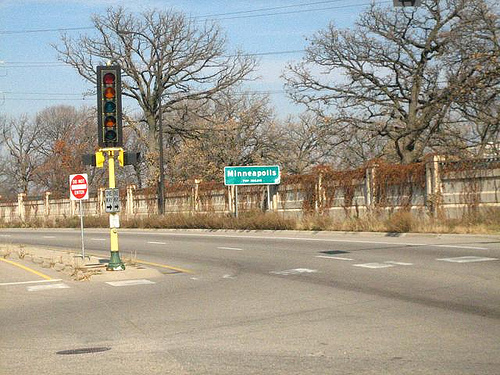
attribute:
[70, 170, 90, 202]
sign — red, white 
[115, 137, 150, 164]
sign — peatonal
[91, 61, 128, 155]
light — off, traffic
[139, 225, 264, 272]
lines — white, dotted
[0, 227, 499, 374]
street — empty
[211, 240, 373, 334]
street — paved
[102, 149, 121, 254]
pole — yellow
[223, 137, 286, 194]
sign — peatonal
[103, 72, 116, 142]
lights — dark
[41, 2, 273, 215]
tree — bare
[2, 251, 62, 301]
stripe — yellow 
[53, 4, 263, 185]
tree — bare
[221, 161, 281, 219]
sign — city limits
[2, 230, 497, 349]
street — paved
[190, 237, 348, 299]
street — paved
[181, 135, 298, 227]
sign — long, rectangular 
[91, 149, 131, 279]
pole — green, yellow